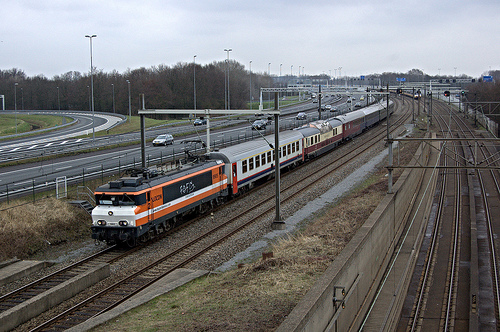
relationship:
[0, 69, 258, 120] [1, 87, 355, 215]
trees on back of road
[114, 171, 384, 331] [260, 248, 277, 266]
grass and a tree stump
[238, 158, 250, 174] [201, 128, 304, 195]
window in a train car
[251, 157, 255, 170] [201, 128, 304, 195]
window in a train car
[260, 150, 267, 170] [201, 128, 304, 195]
window in a train car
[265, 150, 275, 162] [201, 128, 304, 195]
window in a train car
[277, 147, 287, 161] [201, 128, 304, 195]
window in a train car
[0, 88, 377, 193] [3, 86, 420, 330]
highway next to rail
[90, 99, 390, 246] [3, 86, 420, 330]
train on rail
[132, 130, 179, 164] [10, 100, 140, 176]
car driving on highway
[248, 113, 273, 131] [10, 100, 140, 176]
car driving on highway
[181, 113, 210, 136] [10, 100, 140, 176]
car driving on highway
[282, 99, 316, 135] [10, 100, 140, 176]
car driving on highway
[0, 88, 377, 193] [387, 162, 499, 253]
highway next to tracks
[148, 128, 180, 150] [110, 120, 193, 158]
car on motorway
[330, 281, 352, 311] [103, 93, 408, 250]
signal direct trains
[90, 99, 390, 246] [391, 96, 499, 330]
train on rail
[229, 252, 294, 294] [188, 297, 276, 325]
grass with dirt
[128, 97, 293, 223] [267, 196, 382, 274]
rails on soil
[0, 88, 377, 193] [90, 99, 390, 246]
highway near train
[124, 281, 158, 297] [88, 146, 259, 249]
rail line used by train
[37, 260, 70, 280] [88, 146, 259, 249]
rail line used by train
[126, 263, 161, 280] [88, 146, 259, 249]
rail line used by train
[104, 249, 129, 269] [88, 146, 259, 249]
rail line used by train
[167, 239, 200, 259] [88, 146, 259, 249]
rail line used by train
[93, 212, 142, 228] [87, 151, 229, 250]
headlights on engine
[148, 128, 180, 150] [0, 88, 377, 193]
car on highway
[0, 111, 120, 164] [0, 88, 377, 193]
road converged with highway